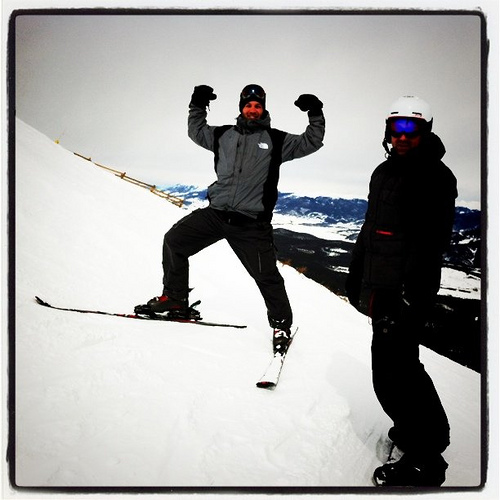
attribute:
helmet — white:
[386, 94, 434, 135]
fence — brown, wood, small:
[57, 143, 185, 210]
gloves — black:
[191, 84, 323, 113]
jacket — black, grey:
[188, 106, 325, 224]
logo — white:
[258, 142, 268, 151]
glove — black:
[190, 85, 218, 107]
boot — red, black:
[147, 293, 190, 310]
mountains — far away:
[143, 183, 482, 376]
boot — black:
[375, 452, 450, 485]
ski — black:
[37, 296, 248, 328]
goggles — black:
[240, 89, 266, 102]